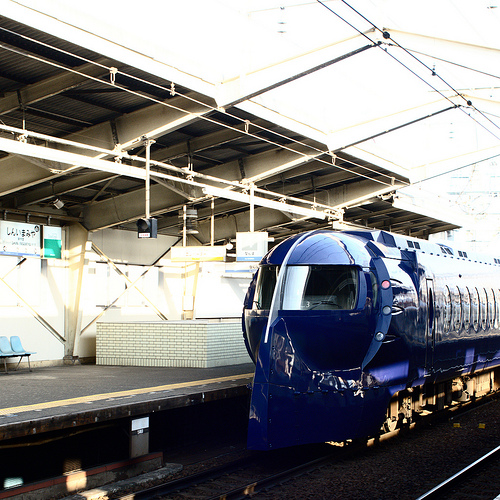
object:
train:
[242, 221, 499, 456]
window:
[252, 260, 279, 310]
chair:
[10, 333, 34, 371]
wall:
[0, 254, 251, 369]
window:
[444, 284, 454, 331]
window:
[473, 287, 482, 332]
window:
[426, 287, 434, 332]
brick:
[193, 336, 207, 343]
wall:
[95, 319, 205, 369]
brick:
[191, 357, 198, 368]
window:
[411, 239, 423, 250]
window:
[280, 263, 358, 312]